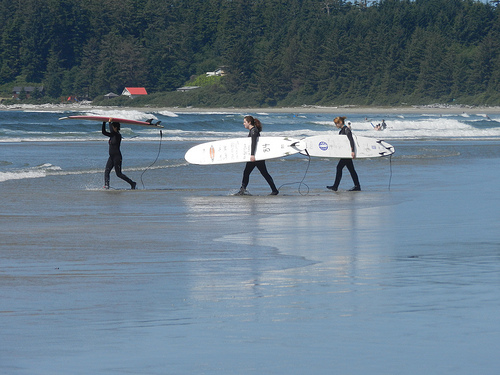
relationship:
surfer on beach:
[101, 118, 138, 190] [395, 114, 499, 374]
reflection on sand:
[185, 198, 392, 304] [0, 196, 499, 374]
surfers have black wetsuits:
[101, 118, 138, 190] [100, 134, 138, 191]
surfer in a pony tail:
[236, 116, 279, 195] [245, 114, 261, 130]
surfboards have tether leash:
[185, 135, 308, 165] [280, 149, 314, 201]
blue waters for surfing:
[0, 111, 55, 169] [0, 111, 499, 198]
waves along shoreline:
[400, 116, 499, 140] [394, 114, 498, 160]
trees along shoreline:
[227, 0, 499, 113] [155, 105, 500, 118]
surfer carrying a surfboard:
[235, 116, 278, 202] [185, 135, 308, 165]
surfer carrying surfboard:
[327, 114, 362, 193] [297, 133, 396, 159]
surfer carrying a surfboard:
[101, 118, 138, 190] [61, 112, 164, 127]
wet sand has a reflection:
[0, 196, 499, 374] [185, 198, 392, 304]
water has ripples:
[0, 111, 55, 169] [1, 163, 48, 183]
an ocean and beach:
[1, 109, 58, 141] [0, 196, 499, 374]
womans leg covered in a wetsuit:
[327, 158, 348, 193] [327, 126, 362, 192]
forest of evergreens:
[1, 1, 499, 69] [227, 0, 499, 113]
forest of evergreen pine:
[1, 1, 499, 69] [227, 0, 499, 113]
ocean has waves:
[0, 111, 55, 169] [400, 116, 499, 140]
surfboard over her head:
[61, 112, 164, 127] [101, 118, 138, 190]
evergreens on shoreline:
[227, 0, 499, 113] [155, 105, 500, 118]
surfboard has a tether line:
[297, 133, 396, 159] [138, 122, 164, 188]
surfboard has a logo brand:
[297, 133, 396, 159] [318, 141, 329, 152]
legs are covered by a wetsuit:
[256, 160, 281, 195] [236, 129, 280, 200]